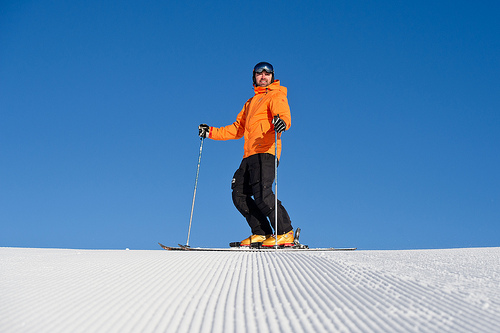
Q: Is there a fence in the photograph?
A: No, there are no fences.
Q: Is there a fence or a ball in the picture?
A: No, there are no fences or balls.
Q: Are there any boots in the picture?
A: Yes, there are boots.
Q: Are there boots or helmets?
A: Yes, there are boots.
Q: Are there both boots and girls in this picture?
A: No, there are boots but no girls.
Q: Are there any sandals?
A: No, there are no sandals.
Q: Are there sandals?
A: No, there are no sandals.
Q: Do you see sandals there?
A: No, there are no sandals.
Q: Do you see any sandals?
A: No, there are no sandals.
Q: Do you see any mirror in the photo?
A: No, there are no mirrors.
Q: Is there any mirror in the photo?
A: No, there are no mirrors.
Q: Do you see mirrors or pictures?
A: No, there are no mirrors or pictures.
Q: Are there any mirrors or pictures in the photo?
A: No, there are no mirrors or pictures.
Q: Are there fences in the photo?
A: No, there are no fences.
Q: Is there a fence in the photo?
A: No, there are no fences.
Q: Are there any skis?
A: Yes, there are skis.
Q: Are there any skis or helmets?
A: Yes, there are skis.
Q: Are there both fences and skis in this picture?
A: No, there are skis but no fences.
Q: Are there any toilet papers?
A: No, there are no toilet papers.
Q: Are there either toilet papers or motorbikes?
A: No, there are no toilet papers or motorbikes.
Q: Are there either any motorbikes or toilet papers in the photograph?
A: No, there are no toilet papers or motorbikes.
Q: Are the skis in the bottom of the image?
A: Yes, the skis are in the bottom of the image.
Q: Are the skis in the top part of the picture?
A: No, the skis are in the bottom of the image.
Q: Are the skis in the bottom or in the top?
A: The skis are in the bottom of the image.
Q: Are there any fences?
A: No, there are no fences.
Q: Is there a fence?
A: No, there are no fences.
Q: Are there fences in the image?
A: No, there are no fences.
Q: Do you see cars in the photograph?
A: No, there are no cars.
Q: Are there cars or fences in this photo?
A: No, there are no cars or fences.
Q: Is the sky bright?
A: Yes, the sky is bright.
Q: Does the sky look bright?
A: Yes, the sky is bright.